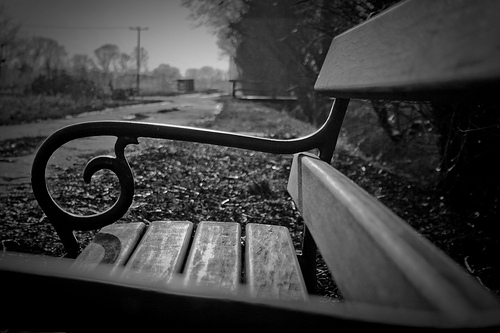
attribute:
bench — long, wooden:
[106, 19, 470, 321]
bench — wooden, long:
[51, 90, 389, 327]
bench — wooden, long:
[24, 44, 440, 329]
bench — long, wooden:
[35, 70, 455, 330]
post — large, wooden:
[100, 25, 170, 101]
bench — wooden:
[10, 81, 446, 300]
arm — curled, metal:
[32, 74, 291, 247]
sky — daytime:
[44, 10, 211, 100]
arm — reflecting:
[43, 85, 321, 247]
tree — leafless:
[26, 32, 156, 112]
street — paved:
[90, 73, 228, 160]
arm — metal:
[21, 93, 303, 226]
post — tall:
[121, 17, 173, 98]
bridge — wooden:
[221, 66, 295, 129]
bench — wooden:
[39, 10, 497, 331]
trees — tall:
[1, 17, 173, 127]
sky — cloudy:
[125, 6, 237, 96]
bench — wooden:
[41, 50, 497, 330]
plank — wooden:
[192, 225, 271, 299]